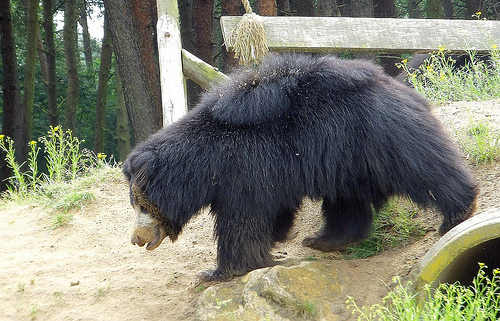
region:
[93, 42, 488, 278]
The bear is walking.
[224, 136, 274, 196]
The bear is black.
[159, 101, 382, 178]
The bear is furry.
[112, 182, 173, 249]
The face is brown.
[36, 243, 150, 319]
The bear is on the sand.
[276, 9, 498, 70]
A wooden board behind the bear.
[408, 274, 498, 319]
The weeds are green.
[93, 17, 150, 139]
The tree trunks are brown.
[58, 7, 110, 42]
The sky is white.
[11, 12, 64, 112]
The trees are green.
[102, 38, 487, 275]
small black bear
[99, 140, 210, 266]
bear's head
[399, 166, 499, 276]
small tunnel next to the bear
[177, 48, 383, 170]
bear's back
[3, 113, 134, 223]
shrubbery and plants next to the bear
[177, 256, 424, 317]
rock next to the bear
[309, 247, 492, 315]
plants next to the tunnel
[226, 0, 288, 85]
frayed rope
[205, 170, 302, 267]
front legs of the bear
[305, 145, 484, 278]
back legs of the bear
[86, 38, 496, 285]
bear walking down sandy path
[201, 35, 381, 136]
fluffy mound of fur on top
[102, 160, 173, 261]
tan face with white patch under eye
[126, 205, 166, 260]
tan snout with mouth open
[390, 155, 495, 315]
large pipe underneath bear's rear foot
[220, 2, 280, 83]
rope with loose ends on top of bear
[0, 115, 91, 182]
green stems with yellow flowers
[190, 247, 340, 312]
rocks underneath bear's paw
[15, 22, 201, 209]
trees and forest behind bear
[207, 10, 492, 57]
worn plank of wood near bear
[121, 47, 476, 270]
Shaggy bear going slowly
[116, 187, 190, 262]
Bear face dirt patches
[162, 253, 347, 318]
Gray rocks jutting path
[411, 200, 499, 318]
Cement culvert water flows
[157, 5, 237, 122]
Broken fence old wood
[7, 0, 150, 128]
Forest may be bear destination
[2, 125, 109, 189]
Yellow meadow plant flowers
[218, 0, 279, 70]
Braided rope hanging fence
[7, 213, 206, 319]
Pathway sand no foliage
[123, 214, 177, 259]
No teeth seen mouth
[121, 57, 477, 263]
A bear with blue-black fur.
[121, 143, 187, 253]
The bear's head bended.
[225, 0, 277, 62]
A light colored rope hanging down.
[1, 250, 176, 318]
A tan colored dirt path.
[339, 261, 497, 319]
Fresh light green vegetation.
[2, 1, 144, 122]
The bark of an array of trees.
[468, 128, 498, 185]
A small patch of grass.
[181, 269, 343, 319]
A big rock on the ground.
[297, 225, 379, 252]
The bear's back right paw.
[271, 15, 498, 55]
A white washed plank of wood.